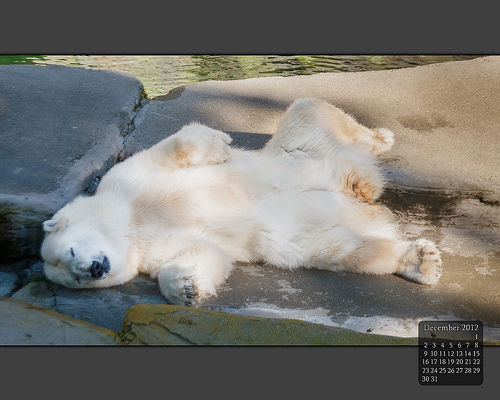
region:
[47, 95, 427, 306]
the bear is laying down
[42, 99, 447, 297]
the bear is laying on his back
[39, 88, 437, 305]
the bear is sleeping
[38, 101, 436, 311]
the bear is dreaming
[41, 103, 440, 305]
the bear is sunbathing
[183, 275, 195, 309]
the bear has nails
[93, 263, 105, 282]
the bear has a black nose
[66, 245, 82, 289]
the eyes are closed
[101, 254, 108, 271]
the mouth is black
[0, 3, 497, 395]
the bear is outside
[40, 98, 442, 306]
polar bear laying on the ground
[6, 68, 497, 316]
rock slab on the ground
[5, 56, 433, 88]
pool of water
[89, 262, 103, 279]
polar bear's black nose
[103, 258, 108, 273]
polar bear's mouth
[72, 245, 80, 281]
polar bear's closed eyes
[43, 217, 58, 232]
polar bear's left ear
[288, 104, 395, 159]
polar bear's left hind leg in the air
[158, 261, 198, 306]
right front paw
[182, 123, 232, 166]
left front paw of bear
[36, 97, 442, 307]
a white bear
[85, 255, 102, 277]
a bear's nose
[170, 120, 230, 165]
left front bear's paw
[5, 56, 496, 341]
slabs of rocks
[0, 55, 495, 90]
greenish colored water beyond the rocks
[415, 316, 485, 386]
a black calendar with white letters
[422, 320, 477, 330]
the words "December 2012" at the top of a calendar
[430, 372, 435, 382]
the number 31 on a December 2012 calendar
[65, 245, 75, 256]
the left eye of a white bear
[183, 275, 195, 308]
the claws of a white bear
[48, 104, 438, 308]
the bear is sunbathing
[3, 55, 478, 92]
the bear is near the water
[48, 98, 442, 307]
the bear is white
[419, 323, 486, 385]
an icon of a calender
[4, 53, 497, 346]
the bear is near rocks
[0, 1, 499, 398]
the photo has a boarder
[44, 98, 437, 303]
the bear is sprawled on the ground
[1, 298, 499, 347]
the rock has moss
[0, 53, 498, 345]
the scene takes place outdoors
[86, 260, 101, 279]
The polar bears nose is black.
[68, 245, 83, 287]
The polar bears eyes are closed.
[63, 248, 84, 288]
The polar bears eyes are small.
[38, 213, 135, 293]
The polar bears face is white and black.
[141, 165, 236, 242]
The polar bears fur is white.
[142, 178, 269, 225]
The polar bears fur is fluffy.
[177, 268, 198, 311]
The polar bears claws are long.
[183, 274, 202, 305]
The polar bears claws are sharp.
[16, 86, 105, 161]
The pavement is grey.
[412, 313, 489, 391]
A calendar is in the right corner of the frame.